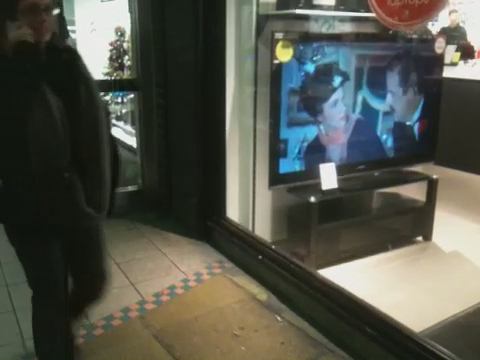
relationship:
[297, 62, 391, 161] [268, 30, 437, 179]
mary poppins showing on tv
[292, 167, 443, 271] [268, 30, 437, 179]
cabinet with a tv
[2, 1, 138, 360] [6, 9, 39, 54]
person on phone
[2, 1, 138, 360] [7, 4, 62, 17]
person in eyeglasses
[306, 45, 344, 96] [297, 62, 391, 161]
black hat on mary poppins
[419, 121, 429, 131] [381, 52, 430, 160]
red rose on lapel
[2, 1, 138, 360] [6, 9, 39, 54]
man on phone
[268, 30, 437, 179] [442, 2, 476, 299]
tv inside store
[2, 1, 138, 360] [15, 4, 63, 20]
person wearing eyeglasses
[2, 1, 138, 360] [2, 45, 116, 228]
person wearing a jacket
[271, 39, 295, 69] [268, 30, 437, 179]
yellow circle on left corner of tv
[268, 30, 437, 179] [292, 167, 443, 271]
television on a small table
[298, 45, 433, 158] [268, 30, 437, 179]
woman and man in a tv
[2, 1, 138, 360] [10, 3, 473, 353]
person walking in room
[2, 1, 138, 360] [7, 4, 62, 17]
person wears eyeglasses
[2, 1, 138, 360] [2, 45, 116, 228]
person wears a winter coat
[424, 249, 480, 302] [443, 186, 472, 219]
floor with tiles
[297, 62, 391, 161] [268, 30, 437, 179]
mary poppins on television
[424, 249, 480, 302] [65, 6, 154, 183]
floor in front of window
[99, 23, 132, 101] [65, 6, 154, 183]
person standing outside window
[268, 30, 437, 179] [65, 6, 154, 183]
television in a window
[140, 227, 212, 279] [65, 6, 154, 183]
floor inside a window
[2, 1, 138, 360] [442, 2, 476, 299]
person standing outside a store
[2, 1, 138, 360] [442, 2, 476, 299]
person exiting a store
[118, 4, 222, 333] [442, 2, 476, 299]
entrance of a store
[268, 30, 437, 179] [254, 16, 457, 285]
tv on display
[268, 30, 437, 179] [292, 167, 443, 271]
tv for a tv stand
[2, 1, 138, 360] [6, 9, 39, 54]
person talking on a phone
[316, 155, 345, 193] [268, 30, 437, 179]
price tag on tv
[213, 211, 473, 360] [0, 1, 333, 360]
molding on outside of building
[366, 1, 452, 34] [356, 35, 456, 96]
advertising sticker on window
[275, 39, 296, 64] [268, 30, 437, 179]
yellow circle on top of tv